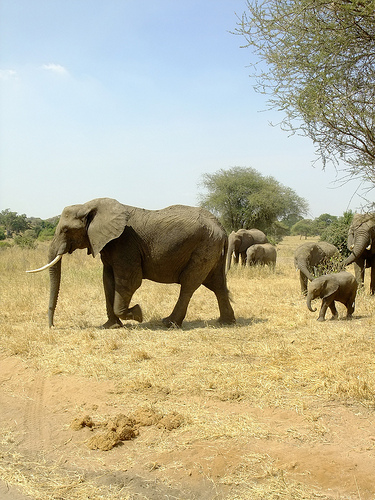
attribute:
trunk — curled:
[299, 290, 319, 320]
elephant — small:
[308, 272, 357, 322]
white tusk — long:
[24, 256, 62, 277]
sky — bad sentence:
[67, 26, 140, 114]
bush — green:
[202, 167, 305, 240]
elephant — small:
[220, 225, 277, 269]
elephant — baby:
[303, 270, 361, 322]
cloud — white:
[1, 58, 97, 138]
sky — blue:
[1, 0, 372, 225]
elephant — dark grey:
[23, 195, 241, 339]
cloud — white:
[35, 55, 76, 85]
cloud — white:
[3, 63, 34, 100]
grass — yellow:
[20, 267, 315, 335]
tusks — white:
[19, 252, 64, 274]